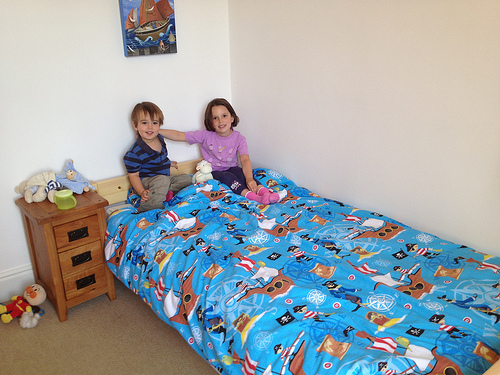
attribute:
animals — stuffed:
[8, 157, 100, 209]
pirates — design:
[429, 314, 472, 344]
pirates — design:
[301, 230, 341, 253]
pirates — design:
[237, 286, 246, 292]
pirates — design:
[392, 267, 409, 274]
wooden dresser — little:
[13, 192, 113, 319]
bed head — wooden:
[85, 154, 285, 209]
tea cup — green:
[54, 187, 76, 211]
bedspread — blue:
[212, 207, 435, 341]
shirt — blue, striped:
[105, 126, 177, 179]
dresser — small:
[15, 186, 115, 315]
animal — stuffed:
[0, 282, 55, 325]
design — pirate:
[342, 257, 437, 303]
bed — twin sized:
[115, 152, 481, 354]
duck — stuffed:
[3, 282, 43, 331]